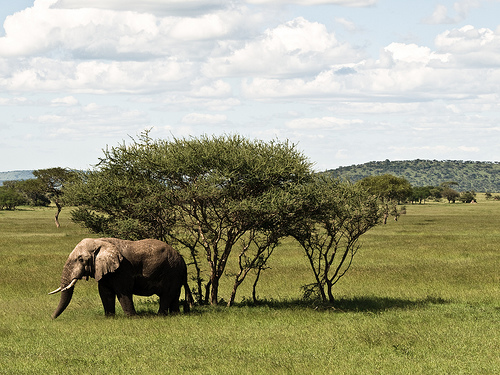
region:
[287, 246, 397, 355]
the grass is green and visible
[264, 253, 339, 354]
the grass is green and visible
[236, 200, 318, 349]
the grass is green and visible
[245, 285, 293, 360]
the grass is green and visible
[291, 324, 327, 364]
the grass is green and visible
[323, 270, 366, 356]
the grass is green and visible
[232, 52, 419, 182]
the sky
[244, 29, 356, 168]
the sky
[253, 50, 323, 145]
the sky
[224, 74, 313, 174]
the sky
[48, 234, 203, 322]
an elephant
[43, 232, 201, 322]
a elephant standing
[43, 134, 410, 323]
an elephant stands next to a tree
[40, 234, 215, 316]
an elephant in the wild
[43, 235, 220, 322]
the elephant has tusks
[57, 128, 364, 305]
a large brush like tree is next to the elephant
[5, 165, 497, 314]
small trees are scattered through the scene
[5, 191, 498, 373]
a large field with small trees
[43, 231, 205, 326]
the elephant is alone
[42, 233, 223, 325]
the elephant is grey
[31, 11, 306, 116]
white and blue sky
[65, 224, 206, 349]
elephant is under tree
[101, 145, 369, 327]
tree is small and green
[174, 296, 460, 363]
grass is thick and green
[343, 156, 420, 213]
group of trees in distance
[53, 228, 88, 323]
elephant has long nose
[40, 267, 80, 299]
elephant has two white tusks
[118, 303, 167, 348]
grass under elephant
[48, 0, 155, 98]
puffy clouds in sky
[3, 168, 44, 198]
tall hills in background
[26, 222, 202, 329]
elephant standing in grass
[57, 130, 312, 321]
tree in field behind elephant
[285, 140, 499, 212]
tree covered hill in distance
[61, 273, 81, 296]
elephant husk on left of trunk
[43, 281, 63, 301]
husk to right of trunk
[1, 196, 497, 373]
open field of grass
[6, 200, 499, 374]
grass in field is green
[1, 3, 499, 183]
sky is partly cloudy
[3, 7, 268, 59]
cloud in blue sky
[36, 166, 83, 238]
small tree in field